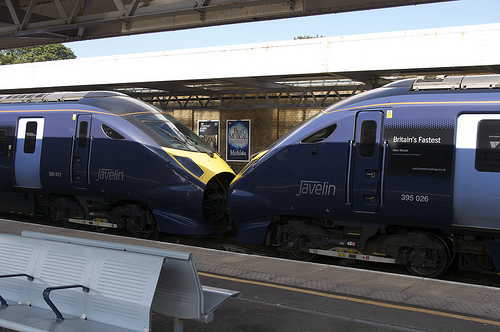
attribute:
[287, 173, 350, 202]
white sticker — yellow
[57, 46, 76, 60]
leaves — green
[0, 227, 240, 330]
seats — metal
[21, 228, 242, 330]
bench — metal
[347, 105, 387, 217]
door — side door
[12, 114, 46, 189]
door — passenger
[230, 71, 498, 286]
train — blue, yellow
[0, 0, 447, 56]
metal rafters — large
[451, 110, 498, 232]
door — passenger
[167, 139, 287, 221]
train — yellow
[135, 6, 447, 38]
sky — clear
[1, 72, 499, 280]
cars — connected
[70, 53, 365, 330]
train — javelin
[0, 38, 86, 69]
tree — green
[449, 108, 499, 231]
doors — white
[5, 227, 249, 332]
bench — white, metal